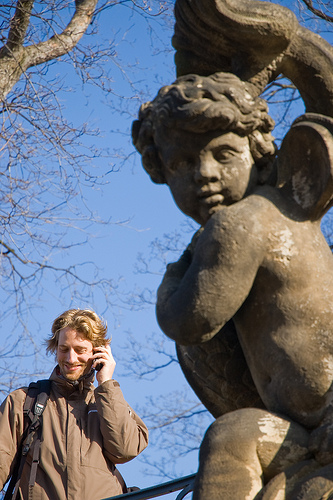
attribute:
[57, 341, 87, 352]
eyebrows — light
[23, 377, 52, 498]
strap — black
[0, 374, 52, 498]
bag — black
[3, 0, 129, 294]
leafless tree —  leafless, large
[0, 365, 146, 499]
coat — tan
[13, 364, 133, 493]
jacket — brown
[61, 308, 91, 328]
hair — wavy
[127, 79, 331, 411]
statue — concrete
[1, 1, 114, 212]
tree — thick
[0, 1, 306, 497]
sky — blue, clear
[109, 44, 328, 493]
statue — concrete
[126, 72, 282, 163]
hair — wavy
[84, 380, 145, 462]
sleeves — brown, long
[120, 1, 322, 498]
statue — stone